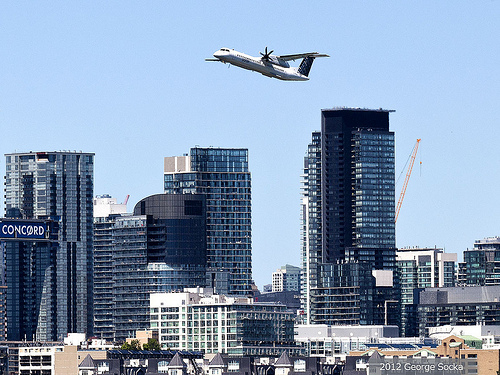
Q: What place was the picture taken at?
A: It was taken at the city.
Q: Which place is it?
A: It is a city.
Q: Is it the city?
A: Yes, it is the city.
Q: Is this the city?
A: Yes, it is the city.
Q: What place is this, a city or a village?
A: It is a city.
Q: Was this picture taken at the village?
A: No, the picture was taken in the city.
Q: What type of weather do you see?
A: It is clear.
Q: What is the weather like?
A: It is clear.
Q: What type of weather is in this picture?
A: It is clear.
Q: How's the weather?
A: It is clear.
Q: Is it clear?
A: Yes, it is clear.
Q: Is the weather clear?
A: Yes, it is clear.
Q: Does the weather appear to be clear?
A: Yes, it is clear.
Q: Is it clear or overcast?
A: It is clear.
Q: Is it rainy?
A: No, it is clear.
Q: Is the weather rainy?
A: No, it is clear.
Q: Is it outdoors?
A: Yes, it is outdoors.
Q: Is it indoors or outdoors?
A: It is outdoors.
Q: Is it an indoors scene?
A: No, it is outdoors.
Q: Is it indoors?
A: No, it is outdoors.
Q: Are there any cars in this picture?
A: No, there are no cars.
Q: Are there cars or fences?
A: No, there are no cars or fences.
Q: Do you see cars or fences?
A: No, there are no cars or fences.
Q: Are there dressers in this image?
A: No, there are no dressers.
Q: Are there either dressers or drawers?
A: No, there are no dressers or drawers.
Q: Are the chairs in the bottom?
A: Yes, the chairs are in the bottom of the image.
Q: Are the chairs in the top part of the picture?
A: No, the chairs are in the bottom of the image.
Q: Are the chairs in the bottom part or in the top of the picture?
A: The chairs are in the bottom of the image.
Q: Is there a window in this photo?
A: Yes, there are windows.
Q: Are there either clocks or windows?
A: Yes, there are windows.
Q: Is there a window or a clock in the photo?
A: Yes, there are windows.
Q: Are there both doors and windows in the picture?
A: No, there are windows but no doors.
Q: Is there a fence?
A: No, there are no fences.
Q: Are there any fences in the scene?
A: No, there are no fences.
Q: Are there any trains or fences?
A: No, there are no fences or trains.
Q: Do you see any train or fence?
A: No, there are no fences or trains.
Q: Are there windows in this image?
A: Yes, there are windows.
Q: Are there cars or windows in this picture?
A: Yes, there are windows.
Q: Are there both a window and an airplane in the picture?
A: Yes, there are both a window and an airplane.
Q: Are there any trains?
A: No, there are no trains.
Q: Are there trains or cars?
A: No, there are no trains or cars.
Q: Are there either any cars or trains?
A: No, there are no trains or cars.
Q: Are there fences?
A: No, there are no fences.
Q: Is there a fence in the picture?
A: No, there are no fences.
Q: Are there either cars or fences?
A: No, there are no fences or cars.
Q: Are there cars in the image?
A: No, there are no cars.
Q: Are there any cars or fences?
A: No, there are no cars or fences.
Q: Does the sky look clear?
A: Yes, the sky is clear.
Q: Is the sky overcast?
A: No, the sky is clear.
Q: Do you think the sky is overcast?
A: No, the sky is clear.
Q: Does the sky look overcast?
A: No, the sky is clear.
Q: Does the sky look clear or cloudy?
A: The sky is clear.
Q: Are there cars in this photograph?
A: No, there are no cars.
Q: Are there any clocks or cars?
A: No, there are no cars or clocks.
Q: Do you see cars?
A: No, there are no cars.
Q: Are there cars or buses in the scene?
A: No, there are no cars or buses.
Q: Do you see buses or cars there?
A: No, there are no cars or buses.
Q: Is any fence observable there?
A: No, there are no fences.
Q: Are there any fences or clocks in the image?
A: No, there are no fences or clocks.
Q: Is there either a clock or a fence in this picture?
A: No, there are no fences or clocks.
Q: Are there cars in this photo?
A: No, there are no cars.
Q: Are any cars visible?
A: No, there are no cars.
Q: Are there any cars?
A: No, there are no cars.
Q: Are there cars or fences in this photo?
A: No, there are no cars or fences.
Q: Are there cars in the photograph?
A: No, there are no cars.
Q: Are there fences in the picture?
A: No, there are no fences.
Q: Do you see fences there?
A: No, there are no fences.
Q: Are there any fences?
A: No, there are no fences.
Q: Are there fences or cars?
A: No, there are no fences or cars.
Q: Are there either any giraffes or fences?
A: No, there are no fences or giraffes.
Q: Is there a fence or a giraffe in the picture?
A: No, there are no fences or giraffes.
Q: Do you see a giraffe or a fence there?
A: No, there are no fences or giraffes.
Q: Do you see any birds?
A: No, there are no birds.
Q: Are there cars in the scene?
A: No, there are no cars.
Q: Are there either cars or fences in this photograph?
A: No, there are no cars or fences.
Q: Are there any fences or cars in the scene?
A: No, there are no cars or fences.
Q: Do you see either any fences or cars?
A: No, there are no cars or fences.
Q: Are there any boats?
A: No, there are no boats.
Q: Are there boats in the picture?
A: No, there are no boats.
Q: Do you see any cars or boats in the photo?
A: No, there are no boats or cars.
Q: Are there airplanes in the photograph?
A: Yes, there is an airplane.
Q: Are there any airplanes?
A: Yes, there is an airplane.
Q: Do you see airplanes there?
A: Yes, there is an airplane.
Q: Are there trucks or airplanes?
A: Yes, there is an airplane.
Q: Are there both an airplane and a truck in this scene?
A: No, there is an airplane but no trucks.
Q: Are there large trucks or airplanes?
A: Yes, there is a large airplane.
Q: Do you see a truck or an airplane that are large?
A: Yes, the airplane is large.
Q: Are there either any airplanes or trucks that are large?
A: Yes, the airplane is large.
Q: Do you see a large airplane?
A: Yes, there is a large airplane.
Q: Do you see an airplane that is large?
A: Yes, there is an airplane that is large.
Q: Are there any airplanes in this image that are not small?
A: Yes, there is a large airplane.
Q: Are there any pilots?
A: No, there are no pilots.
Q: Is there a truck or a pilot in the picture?
A: No, there are no pilots or trucks.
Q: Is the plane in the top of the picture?
A: Yes, the plane is in the top of the image.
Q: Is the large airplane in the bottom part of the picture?
A: No, the airplane is in the top of the image.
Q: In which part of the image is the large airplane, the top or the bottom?
A: The plane is in the top of the image.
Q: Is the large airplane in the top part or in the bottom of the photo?
A: The plane is in the top of the image.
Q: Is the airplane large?
A: Yes, the airplane is large.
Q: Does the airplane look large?
A: Yes, the airplane is large.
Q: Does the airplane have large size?
A: Yes, the airplane is large.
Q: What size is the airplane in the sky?
A: The plane is large.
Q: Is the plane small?
A: No, the plane is large.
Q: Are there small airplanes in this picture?
A: No, there is an airplane but it is large.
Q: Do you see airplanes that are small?
A: No, there is an airplane but it is large.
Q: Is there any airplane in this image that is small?
A: No, there is an airplane but it is large.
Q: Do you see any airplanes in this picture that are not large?
A: No, there is an airplane but it is large.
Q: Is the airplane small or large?
A: The airplane is large.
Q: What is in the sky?
A: The plane is in the sky.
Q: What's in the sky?
A: The plane is in the sky.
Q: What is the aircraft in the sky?
A: The aircraft is an airplane.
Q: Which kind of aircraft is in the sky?
A: The aircraft is an airplane.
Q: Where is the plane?
A: The plane is in the sky.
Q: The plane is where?
A: The plane is in the sky.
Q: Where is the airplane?
A: The plane is in the sky.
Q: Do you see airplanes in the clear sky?
A: Yes, there is an airplane in the sky.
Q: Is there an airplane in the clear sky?
A: Yes, there is an airplane in the sky.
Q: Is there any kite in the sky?
A: No, there is an airplane in the sky.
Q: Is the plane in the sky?
A: Yes, the plane is in the sky.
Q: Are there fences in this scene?
A: No, there are no fences.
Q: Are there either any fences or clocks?
A: No, there are no fences or clocks.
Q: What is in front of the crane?
A: The building is in front of the crane.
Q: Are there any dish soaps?
A: No, there are no dish soaps.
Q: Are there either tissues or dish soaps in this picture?
A: No, there are no dish soaps or tissues.